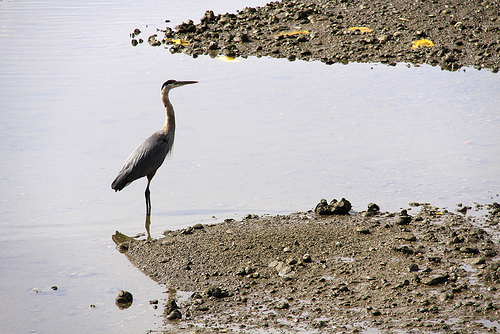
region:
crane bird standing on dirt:
[110, 47, 200, 243]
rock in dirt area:
[277, 40, 317, 80]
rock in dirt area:
[432, 36, 472, 66]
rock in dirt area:
[196, 9, 218, 30]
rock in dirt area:
[425, 258, 448, 283]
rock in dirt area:
[111, 283, 137, 305]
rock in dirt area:
[183, 274, 229, 312]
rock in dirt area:
[390, 205, 422, 237]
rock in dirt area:
[357, 191, 375, 225]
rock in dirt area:
[318, 193, 371, 231]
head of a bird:
[159, 73, 196, 93]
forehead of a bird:
[163, 79, 182, 83]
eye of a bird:
[166, 78, 177, 88]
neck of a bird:
[156, 90, 178, 128]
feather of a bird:
[103, 157, 140, 194]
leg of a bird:
[135, 194, 163, 250]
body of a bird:
[126, 125, 174, 172]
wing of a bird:
[125, 129, 166, 171]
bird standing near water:
[93, 48, 217, 250]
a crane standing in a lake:
[70, 72, 237, 282]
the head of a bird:
[143, 66, 183, 108]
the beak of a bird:
[166, 66, 211, 96]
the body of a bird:
[98, 132, 194, 192]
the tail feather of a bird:
[100, 147, 147, 204]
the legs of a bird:
[128, 171, 173, 216]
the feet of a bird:
[141, 220, 168, 245]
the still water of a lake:
[267, 89, 377, 174]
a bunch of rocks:
[250, 231, 336, 297]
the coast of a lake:
[76, 229, 168, 286]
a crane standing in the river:
[117, 72, 184, 247]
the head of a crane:
[160, 66, 200, 101]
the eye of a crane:
[163, 76, 175, 88]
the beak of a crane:
[173, 79, 203, 91]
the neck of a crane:
[152, 87, 184, 138]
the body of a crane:
[101, 121, 179, 190]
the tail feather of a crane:
[111, 166, 131, 196]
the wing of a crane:
[137, 147, 164, 168]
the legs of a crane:
[137, 177, 161, 242]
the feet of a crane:
[135, 230, 165, 252]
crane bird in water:
[107, 67, 203, 248]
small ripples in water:
[28, 35, 89, 85]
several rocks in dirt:
[194, 23, 225, 39]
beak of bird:
[175, 78, 200, 86]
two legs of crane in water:
[130, 183, 164, 240]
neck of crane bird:
[145, 97, 191, 134]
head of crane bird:
[160, 75, 200, 103]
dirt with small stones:
[192, 238, 218, 257]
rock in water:
[110, 286, 140, 313]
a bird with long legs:
[111, 75, 210, 247]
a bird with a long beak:
[107, 71, 202, 241]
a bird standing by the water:
[108, 73, 204, 245]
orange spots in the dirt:
[166, 22, 451, 61]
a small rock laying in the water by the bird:
[110, 285, 137, 316]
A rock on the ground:
[393, 31, 401, 36]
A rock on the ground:
[302, 250, 309, 257]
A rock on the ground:
[286, 259, 296, 262]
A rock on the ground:
[245, 263, 252, 270]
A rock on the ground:
[406, 260, 417, 273]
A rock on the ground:
[426, 253, 441, 262]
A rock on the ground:
[419, 245, 426, 251]